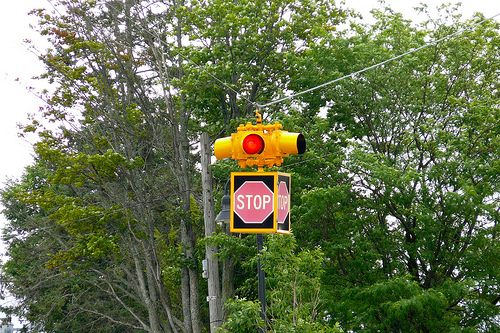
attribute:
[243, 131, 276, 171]
light — red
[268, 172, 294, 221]
border — yellow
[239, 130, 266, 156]
light — red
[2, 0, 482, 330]
trees — green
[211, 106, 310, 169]
framework — yellow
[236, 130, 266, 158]
light — traffic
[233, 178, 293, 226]
signs — stop, pink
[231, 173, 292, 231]
signs — stop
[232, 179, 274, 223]
sign — red, whtie, stop, white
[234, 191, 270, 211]
word — "stop"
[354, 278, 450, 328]
leaves — green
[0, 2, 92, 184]
sky — white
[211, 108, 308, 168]
lights — three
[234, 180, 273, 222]
sign — red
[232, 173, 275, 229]
background — black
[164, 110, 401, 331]
tree — green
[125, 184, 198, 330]
branches — brown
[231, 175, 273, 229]
sign — stop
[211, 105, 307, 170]
light — bright, yellow, stop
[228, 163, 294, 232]
stopsign — stop light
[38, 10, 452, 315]
leafy trees — Tall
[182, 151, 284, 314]
pole — Power , mixed 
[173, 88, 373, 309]
power line — holding ,  light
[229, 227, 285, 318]
post — Black metal light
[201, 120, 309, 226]
light — Black street light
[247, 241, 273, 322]
pole — side  light, Box 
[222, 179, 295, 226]
signs — hanging stop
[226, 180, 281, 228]
word — STOP,  white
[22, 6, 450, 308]
green trees — group , big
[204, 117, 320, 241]
light —  red stop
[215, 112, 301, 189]
lights — hanging street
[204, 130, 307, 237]
lights — hanging yellow street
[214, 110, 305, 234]
lights — wire holding the street 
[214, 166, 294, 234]
stop sign — black area  the street 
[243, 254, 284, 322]
pole — black 